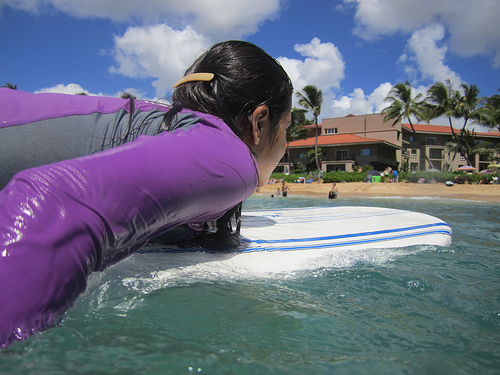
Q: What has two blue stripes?
A: Surfboard.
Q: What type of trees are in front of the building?
A: Palm trees.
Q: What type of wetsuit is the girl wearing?
A: Purple and gray.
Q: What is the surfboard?
A: In the ocean.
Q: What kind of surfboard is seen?
A: White and blue.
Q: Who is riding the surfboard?
A: The girl.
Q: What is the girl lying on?
A: Surfboard.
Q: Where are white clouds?
A: In the sky.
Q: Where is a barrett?
A: In girl's hair.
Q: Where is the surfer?
A: In the ocean.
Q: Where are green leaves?
A: On palm trees.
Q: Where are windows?
A: On a building.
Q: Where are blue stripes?
A: On surfboard.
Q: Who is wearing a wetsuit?
A: Girl surfing.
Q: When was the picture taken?
A: During the daytime.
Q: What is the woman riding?
A: A surfboard.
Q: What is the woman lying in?
A: The ocean.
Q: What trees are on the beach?
A: Palm trees.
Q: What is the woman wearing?
A: A wetsuit.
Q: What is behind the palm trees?
A: A hotel.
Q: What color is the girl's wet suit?
A: Purple and gray.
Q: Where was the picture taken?
A: The beach.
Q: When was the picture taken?
A: During the day.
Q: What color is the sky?
A: Blue.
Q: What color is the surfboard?
A: White and blue.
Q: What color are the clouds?
A: White.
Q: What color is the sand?
A: Brown.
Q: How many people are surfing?
A: 1.